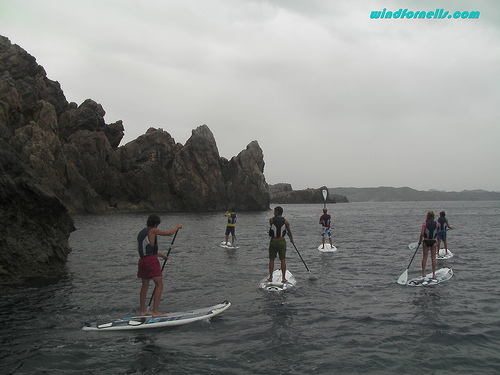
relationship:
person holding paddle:
[417, 211, 439, 278] [395, 232, 425, 287]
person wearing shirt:
[417, 211, 439, 278] [418, 217, 444, 247]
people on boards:
[128, 192, 460, 312] [220, 257, 458, 294]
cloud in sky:
[157, 8, 326, 98] [1, 0, 484, 190]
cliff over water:
[231, 137, 268, 196] [5, 200, 481, 358]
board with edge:
[78, 298, 236, 340] [102, 313, 217, 333]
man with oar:
[313, 174, 361, 276] [289, 237, 320, 282]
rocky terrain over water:
[8, 45, 279, 220] [1, 174, 499, 374]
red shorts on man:
[135, 255, 160, 280] [134, 214, 181, 320]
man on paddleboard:
[136, 214, 181, 317] [84, 293, 236, 329]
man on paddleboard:
[267, 206, 289, 282] [264, 260, 293, 300]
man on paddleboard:
[224, 210, 237, 246] [214, 237, 237, 249]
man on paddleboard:
[318, 208, 333, 249] [316, 240, 340, 255]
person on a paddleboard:
[417, 211, 439, 278] [390, 261, 453, 290]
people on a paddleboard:
[437, 211, 453, 255] [428, 245, 455, 266]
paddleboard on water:
[258, 268, 297, 292] [1, 174, 499, 374]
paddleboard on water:
[316, 243, 335, 252] [1, 174, 499, 374]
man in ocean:
[136, 214, 181, 317] [10, 183, 499, 373]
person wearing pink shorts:
[417, 211, 439, 278] [131, 255, 165, 281]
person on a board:
[417, 211, 439, 278] [81, 300, 231, 331]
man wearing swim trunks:
[224, 210, 237, 246] [264, 239, 291, 259]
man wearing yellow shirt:
[223, 210, 238, 256] [225, 210, 237, 230]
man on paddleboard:
[223, 210, 238, 256] [214, 239, 237, 249]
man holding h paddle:
[318, 208, 333, 249] [311, 175, 333, 211]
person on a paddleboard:
[417, 211, 439, 278] [395, 272, 453, 288]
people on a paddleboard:
[437, 211, 453, 255] [430, 246, 450, 267]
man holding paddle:
[318, 208, 333, 249] [152, 212, 187, 335]